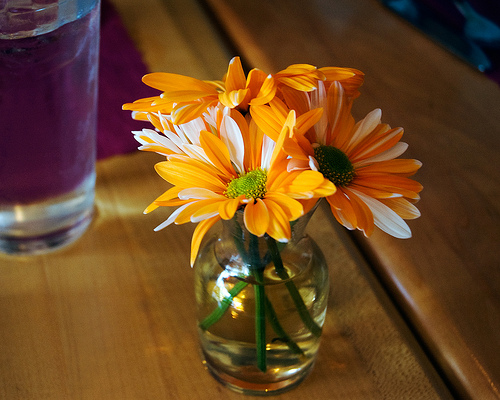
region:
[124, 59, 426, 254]
there are four flowers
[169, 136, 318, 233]
the flowers are orange and white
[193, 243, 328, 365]
the vase holds four flowers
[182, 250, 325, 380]
the vase has water in it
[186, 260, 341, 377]
the water is slightly discolored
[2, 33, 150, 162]
the tablecloth is purple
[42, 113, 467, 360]
the table is made of wood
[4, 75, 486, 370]
the table is brown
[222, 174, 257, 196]
the flower buds are green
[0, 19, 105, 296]
there is a glass of water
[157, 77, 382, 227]
orange and white flowers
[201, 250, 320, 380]
a vase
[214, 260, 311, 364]
the stems are green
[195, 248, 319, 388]
the vase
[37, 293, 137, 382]
the brown table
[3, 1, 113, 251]
a glass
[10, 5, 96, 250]
glass on the table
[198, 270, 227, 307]
water in the vase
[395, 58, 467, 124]
the counter is brown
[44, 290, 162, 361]
a wooden table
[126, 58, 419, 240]
the flowers are orange and white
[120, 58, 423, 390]
the flowers are in a vase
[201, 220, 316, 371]
the stems are in water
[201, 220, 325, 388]
the vase has water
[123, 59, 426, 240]
the middle of the flowers are green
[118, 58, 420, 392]
the flowers are two colors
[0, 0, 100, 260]
the glass is full of water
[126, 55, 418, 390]
three flowers in a vase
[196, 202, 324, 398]
the vase is on a table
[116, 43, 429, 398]
flowers in a vase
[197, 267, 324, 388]
stems in the vase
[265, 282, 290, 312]
water in the vase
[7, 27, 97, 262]
glass with purple liqud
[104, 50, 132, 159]
purple on the table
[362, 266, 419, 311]
hole in the table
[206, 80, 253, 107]
pedals on the flower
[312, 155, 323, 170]
yellow spots on the green part of the flower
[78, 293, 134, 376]
part of the table that the vase is on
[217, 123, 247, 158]
white pedal on the flower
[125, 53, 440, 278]
A group of flowers.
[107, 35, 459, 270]
A group of colorful flowers.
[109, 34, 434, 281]
A group of orange and white flowers.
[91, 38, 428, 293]
A group of four flowers.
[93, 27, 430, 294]
A group of four small flowers.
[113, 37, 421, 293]
A group of four colorful flowers.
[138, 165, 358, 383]
A vase with water in it.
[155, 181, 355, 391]
A small vase with water in it.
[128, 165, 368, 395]
A small vase with flowers in it.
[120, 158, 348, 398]
A small vase with water and flowers in it.